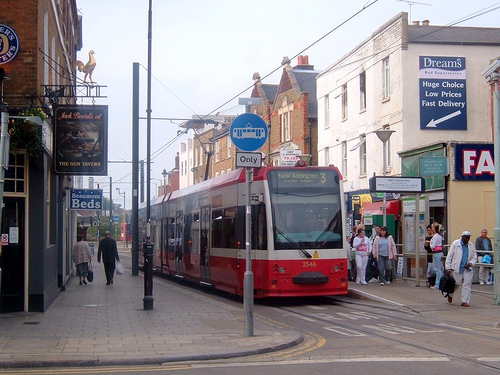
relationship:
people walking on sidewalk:
[70, 231, 120, 282] [68, 281, 136, 350]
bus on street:
[133, 165, 348, 300] [255, 298, 479, 362]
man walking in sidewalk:
[444, 230, 477, 309] [4, 253, 301, 366]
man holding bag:
[95, 229, 121, 286] [115, 258, 127, 283]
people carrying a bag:
[73, 234, 92, 286] [86, 262, 94, 283]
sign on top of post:
[223, 108, 268, 170] [241, 97, 257, 342]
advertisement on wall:
[419, 55, 469, 131] [401, 42, 498, 151]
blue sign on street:
[221, 97, 281, 157] [248, 222, 467, 374]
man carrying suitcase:
[444, 230, 477, 305] [430, 272, 461, 295]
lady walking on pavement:
[348, 224, 373, 285] [348, 268, 491, 373]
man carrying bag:
[95, 229, 121, 286] [113, 259, 128, 281]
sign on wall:
[406, 47, 466, 158] [404, 40, 491, 156]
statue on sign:
[71, 50, 96, 83] [53, 105, 107, 175]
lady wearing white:
[348, 224, 371, 276] [381, 176, 428, 189]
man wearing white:
[444, 230, 477, 305] [436, 231, 496, 331]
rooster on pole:
[73, 49, 100, 84] [41, 81, 106, 100]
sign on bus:
[232, 110, 271, 167] [133, 165, 348, 300]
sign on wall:
[50, 100, 114, 178] [8, 55, 176, 284]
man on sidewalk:
[81, 226, 138, 288] [78, 231, 221, 363]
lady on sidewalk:
[348, 224, 373, 285] [345, 266, 483, 313]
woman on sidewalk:
[370, 222, 397, 280] [345, 266, 483, 313]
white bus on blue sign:
[232, 122, 267, 140] [228, 111, 270, 153]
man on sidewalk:
[95, 229, 121, 286] [11, 242, 296, 362]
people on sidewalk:
[73, 234, 92, 286] [11, 242, 296, 362]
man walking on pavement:
[444, 230, 477, 305] [363, 267, 487, 357]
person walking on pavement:
[426, 222, 443, 290] [395, 286, 427, 298]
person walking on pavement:
[370, 220, 399, 278] [344, 265, 477, 340]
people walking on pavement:
[73, 234, 92, 286] [0, 238, 304, 375]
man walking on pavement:
[95, 229, 121, 286] [0, 238, 304, 375]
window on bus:
[210, 203, 265, 250] [132, 159, 350, 307]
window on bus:
[175, 216, 183, 254] [132, 159, 350, 307]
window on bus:
[160, 216, 174, 250] [132, 159, 350, 307]